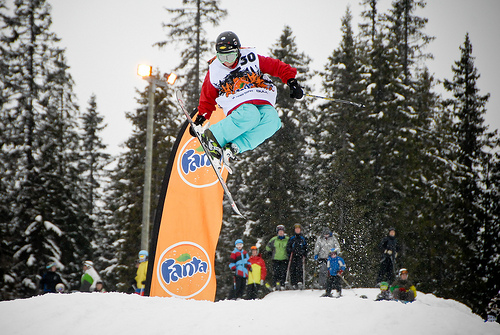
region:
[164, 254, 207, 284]
the word is blue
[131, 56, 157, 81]
the light is on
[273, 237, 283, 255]
the coat is green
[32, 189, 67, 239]
the tree has snow on it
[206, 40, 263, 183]
the person is doing a trick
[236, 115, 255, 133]
the pants are torquise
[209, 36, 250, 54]
the helmet is black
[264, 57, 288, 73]
the shirt is red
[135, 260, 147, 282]
the coat is yellow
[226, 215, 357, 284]
they are watching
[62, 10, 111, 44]
white clouds in blue sky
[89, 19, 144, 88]
white clouds in blue sky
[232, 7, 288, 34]
white clouds in blue sky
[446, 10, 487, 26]
white clouds in blue sky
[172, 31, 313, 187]
person doing jump with skis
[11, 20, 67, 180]
tall trees with green leaves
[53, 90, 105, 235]
tall trees with green leaves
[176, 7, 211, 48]
tall trees with green leaves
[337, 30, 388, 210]
tall trees with green leaves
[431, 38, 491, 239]
tall trees with green leaves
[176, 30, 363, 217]
skier performing jump in air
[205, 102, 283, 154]
skier wearing turquoise ski pants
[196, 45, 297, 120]
skier wearing red and white jacket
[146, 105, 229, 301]
tall orange Fanta banner on ski slope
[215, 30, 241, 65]
skier wearing black helmet and goggles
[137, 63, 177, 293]
outdoor lighting on pole is turned on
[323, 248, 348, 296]
young standing spectator wearing blue jacket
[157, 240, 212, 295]
Fanta logo is white circle with green leaf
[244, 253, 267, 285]
spectator is wearing red and yellow jacket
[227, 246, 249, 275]
spectator is wearing light blue, red, and black jacket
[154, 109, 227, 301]
Orange Fanta advertisement banner.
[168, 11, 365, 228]
Skier grabs his right ski.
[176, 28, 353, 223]
Skier is in mid air.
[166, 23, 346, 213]
Skier is doing a trick.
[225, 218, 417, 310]
Spectators watch a skier.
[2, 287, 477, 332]
A ramp made of snow.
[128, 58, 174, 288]
Tall light post is lit.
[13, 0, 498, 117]
Skies are gray.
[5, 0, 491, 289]
Tall trees in the background.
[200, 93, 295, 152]
Skier wears blue snow pants.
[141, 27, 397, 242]
Skier in the air.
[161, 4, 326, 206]
Man who is skiing.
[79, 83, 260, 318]
Fanta sign in the background.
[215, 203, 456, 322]
People in the snow.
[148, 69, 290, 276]
Ski on the skier.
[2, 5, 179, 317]
Trees in the background.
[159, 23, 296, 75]
Helmet on the skier.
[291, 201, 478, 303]
Snow in the air.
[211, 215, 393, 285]
People wearing coats.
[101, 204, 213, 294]
Fanta logo on the banner.